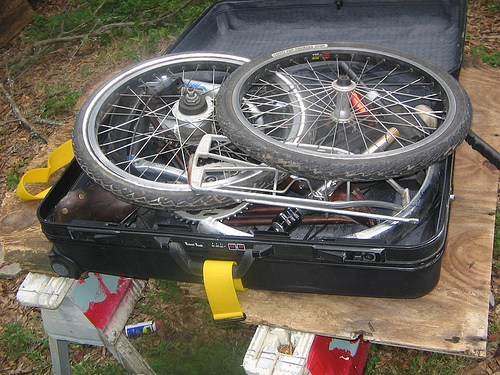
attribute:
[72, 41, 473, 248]
bike — folded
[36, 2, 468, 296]
suitcase — black, grey, open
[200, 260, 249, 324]
strap — yellow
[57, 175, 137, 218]
seat — brown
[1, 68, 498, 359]
wood — ply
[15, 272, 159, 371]
saw horse — peeling, wooden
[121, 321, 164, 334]
can — wd40, engine lubricant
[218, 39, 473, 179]
tire — black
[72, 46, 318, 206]
tire — black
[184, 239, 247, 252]
lock — open